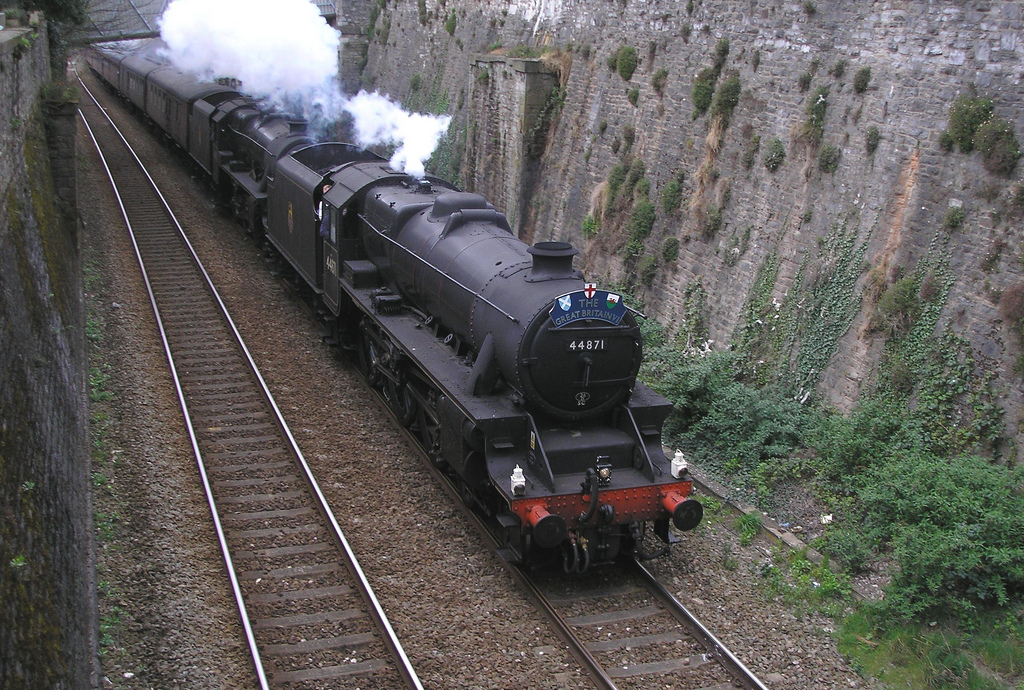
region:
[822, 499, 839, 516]
Small white piece of trash on the ground.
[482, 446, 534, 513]
White pole on the front of the train.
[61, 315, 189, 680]
Thin shrubs of grass on the ground.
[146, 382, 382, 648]
Empty set of train tracks.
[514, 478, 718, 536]
Red paint on the front of the train.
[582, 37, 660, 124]
Green leaves coming out of the wall.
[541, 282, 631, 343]
Letters on the front of the train.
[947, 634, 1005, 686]
Small trail of dirt on the ground.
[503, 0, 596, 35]
White marks on the side of the rocks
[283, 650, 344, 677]
wood on the track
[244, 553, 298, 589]
wood on the track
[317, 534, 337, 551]
wood on the track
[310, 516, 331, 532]
wood on the track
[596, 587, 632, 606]
wood on the track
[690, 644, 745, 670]
wood on the track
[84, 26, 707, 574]
A train on the railroad tracks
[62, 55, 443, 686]
Rails of track on the ground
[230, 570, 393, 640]
Wood railroad ties under the rails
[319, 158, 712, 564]
A steam engine pulling a train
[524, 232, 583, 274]
A smokestack on a steam engine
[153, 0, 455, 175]
Steam from a steam engine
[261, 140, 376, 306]
A coal car on a train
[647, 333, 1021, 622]
Green plants growing near train tracks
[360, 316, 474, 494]
Wheels on a steam engine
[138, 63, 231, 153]
Cars on a train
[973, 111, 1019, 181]
plant growing on wall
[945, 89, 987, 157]
plant growing on wall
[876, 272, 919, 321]
plant growing on wall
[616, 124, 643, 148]
plant growing on wall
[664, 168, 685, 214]
plant growing on wall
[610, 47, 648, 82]
plant growing on wall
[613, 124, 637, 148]
plant growing on wall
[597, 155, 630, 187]
plant growing on wall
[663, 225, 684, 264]
plant growing on wall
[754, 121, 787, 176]
plant growing on wall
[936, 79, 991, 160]
plant growing on wall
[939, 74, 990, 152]
A shrub in the ground.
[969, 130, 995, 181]
A shrub in the ground.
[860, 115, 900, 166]
A shrub in the ground.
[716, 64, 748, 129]
A shrub in the ground.